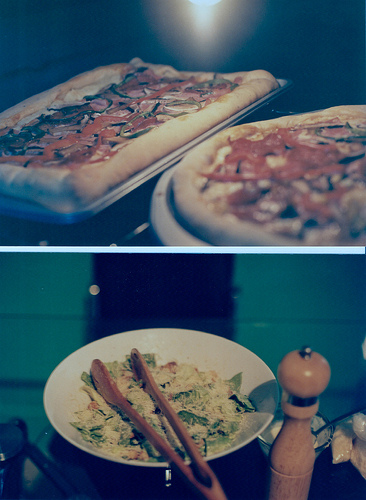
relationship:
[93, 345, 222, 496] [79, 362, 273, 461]
tongs with food